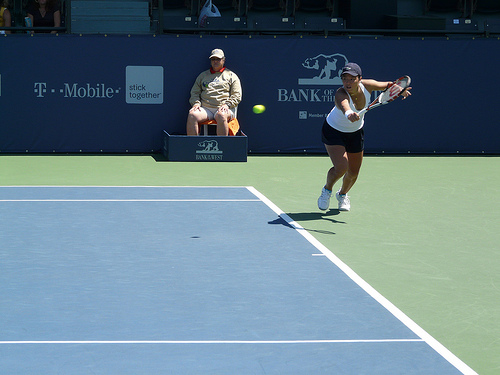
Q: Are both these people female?
A: No, they are both male and female.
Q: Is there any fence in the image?
A: No, there are no fences.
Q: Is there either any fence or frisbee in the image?
A: No, there are no fences or frisbees.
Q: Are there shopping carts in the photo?
A: No, there are no shopping carts.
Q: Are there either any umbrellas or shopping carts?
A: No, there are no shopping carts or umbrellas.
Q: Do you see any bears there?
A: Yes, there is a bear.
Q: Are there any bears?
A: Yes, there is a bear.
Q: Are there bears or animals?
A: Yes, there is a bear.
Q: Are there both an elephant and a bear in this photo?
A: No, there is a bear but no elephants.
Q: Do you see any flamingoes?
A: No, there are no flamingoes.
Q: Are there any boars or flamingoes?
A: No, there are no flamingoes or boars.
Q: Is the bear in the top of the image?
A: Yes, the bear is in the top of the image.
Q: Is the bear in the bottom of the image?
A: No, the bear is in the top of the image.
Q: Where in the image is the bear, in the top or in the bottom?
A: The bear is in the top of the image.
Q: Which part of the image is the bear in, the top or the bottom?
A: The bear is in the top of the image.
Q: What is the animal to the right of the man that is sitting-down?
A: The animal is a bear.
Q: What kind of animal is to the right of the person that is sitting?
A: The animal is a bear.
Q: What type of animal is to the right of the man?
A: The animal is a bear.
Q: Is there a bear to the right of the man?
A: Yes, there is a bear to the right of the man.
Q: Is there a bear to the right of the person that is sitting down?
A: Yes, there is a bear to the right of the man.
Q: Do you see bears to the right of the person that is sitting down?
A: Yes, there is a bear to the right of the man.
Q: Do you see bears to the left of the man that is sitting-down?
A: No, the bear is to the right of the man.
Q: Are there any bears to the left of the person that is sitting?
A: No, the bear is to the right of the man.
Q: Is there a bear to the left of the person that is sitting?
A: No, the bear is to the right of the man.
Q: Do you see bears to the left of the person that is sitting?
A: No, the bear is to the right of the man.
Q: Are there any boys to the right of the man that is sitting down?
A: No, there is a bear to the right of the man.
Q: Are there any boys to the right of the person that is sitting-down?
A: No, there is a bear to the right of the man.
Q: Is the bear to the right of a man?
A: Yes, the bear is to the right of a man.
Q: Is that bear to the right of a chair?
A: No, the bear is to the right of a man.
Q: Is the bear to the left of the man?
A: No, the bear is to the right of the man.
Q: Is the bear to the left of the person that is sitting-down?
A: No, the bear is to the right of the man.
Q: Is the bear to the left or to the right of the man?
A: The bear is to the right of the man.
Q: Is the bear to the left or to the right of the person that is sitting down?
A: The bear is to the right of the man.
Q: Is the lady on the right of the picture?
A: Yes, the lady is on the right of the image.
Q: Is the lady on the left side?
A: No, the lady is on the right of the image.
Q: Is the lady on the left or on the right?
A: The lady is on the right of the image.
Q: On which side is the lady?
A: The lady is on the right of the image.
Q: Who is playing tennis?
A: The lady is playing tennis.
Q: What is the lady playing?
A: The lady is playing tennis.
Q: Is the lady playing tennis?
A: Yes, the lady is playing tennis.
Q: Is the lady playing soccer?
A: No, the lady is playing tennis.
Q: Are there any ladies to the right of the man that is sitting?
A: Yes, there is a lady to the right of the man.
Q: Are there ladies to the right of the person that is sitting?
A: Yes, there is a lady to the right of the man.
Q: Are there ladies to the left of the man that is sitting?
A: No, the lady is to the right of the man.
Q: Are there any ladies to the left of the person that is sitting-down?
A: No, the lady is to the right of the man.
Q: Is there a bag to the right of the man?
A: No, there is a lady to the right of the man.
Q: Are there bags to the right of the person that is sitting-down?
A: No, there is a lady to the right of the man.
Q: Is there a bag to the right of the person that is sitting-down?
A: No, there is a lady to the right of the man.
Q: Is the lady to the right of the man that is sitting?
A: Yes, the lady is to the right of the man.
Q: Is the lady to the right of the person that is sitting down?
A: Yes, the lady is to the right of the man.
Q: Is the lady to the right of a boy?
A: No, the lady is to the right of the man.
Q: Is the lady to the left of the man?
A: No, the lady is to the right of the man.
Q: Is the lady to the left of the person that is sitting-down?
A: No, the lady is to the right of the man.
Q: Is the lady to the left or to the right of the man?
A: The lady is to the right of the man.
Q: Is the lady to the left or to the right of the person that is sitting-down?
A: The lady is to the right of the man.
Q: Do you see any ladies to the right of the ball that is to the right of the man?
A: Yes, there is a lady to the right of the ball.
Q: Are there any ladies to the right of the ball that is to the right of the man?
A: Yes, there is a lady to the right of the ball.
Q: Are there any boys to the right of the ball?
A: No, there is a lady to the right of the ball.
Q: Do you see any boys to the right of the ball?
A: No, there is a lady to the right of the ball.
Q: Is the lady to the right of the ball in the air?
A: Yes, the lady is to the right of the ball.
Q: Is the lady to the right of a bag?
A: No, the lady is to the right of the ball.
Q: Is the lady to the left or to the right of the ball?
A: The lady is to the right of the ball.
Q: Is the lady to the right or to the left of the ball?
A: The lady is to the right of the ball.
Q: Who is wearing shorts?
A: The lady is wearing shorts.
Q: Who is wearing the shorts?
A: The lady is wearing shorts.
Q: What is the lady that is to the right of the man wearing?
A: The lady is wearing shorts.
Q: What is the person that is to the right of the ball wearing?
A: The lady is wearing shorts.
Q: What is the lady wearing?
A: The lady is wearing shorts.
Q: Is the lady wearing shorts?
A: Yes, the lady is wearing shorts.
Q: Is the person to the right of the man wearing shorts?
A: Yes, the lady is wearing shorts.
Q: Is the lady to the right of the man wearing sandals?
A: No, the lady is wearing shorts.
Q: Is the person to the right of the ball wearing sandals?
A: No, the lady is wearing shorts.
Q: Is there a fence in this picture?
A: No, there are no fences.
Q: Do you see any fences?
A: No, there are no fences.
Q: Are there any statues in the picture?
A: No, there are no statues.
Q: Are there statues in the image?
A: No, there are no statues.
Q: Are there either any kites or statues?
A: No, there are no statues or kites.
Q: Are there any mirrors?
A: No, there are no mirrors.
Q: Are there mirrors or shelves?
A: No, there are no mirrors or shelves.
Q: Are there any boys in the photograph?
A: No, there are no boys.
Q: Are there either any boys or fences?
A: No, there are no boys or fences.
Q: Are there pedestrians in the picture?
A: No, there are no pedestrians.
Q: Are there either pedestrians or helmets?
A: No, there are no pedestrians or helmets.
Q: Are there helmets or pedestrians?
A: No, there are no pedestrians or helmets.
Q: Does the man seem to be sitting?
A: Yes, the man is sitting.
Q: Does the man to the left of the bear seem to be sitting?
A: Yes, the man is sitting.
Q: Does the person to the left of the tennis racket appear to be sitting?
A: Yes, the man is sitting.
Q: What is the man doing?
A: The man is sitting.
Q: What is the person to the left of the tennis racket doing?
A: The man is sitting.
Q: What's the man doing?
A: The man is sitting.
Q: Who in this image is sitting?
A: The man is sitting.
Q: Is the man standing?
A: No, the man is sitting.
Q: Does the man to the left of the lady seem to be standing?
A: No, the man is sitting.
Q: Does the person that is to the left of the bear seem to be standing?
A: No, the man is sitting.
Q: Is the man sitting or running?
A: The man is sitting.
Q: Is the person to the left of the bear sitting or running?
A: The man is sitting.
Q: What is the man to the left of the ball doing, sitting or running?
A: The man is sitting.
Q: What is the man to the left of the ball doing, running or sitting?
A: The man is sitting.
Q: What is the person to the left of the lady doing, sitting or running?
A: The man is sitting.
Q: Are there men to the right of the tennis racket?
A: No, the man is to the left of the tennis racket.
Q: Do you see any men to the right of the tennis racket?
A: No, the man is to the left of the tennis racket.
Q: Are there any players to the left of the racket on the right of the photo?
A: No, there is a man to the left of the tennis racket.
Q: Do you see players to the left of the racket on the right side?
A: No, there is a man to the left of the tennis racket.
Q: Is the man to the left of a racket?
A: Yes, the man is to the left of a racket.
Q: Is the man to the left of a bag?
A: No, the man is to the left of a racket.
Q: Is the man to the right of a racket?
A: No, the man is to the left of a racket.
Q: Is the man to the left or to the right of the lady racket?
A: The man is to the left of the tennis racket.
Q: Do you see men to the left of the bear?
A: Yes, there is a man to the left of the bear.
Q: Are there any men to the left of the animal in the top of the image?
A: Yes, there is a man to the left of the bear.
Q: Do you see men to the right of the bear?
A: No, the man is to the left of the bear.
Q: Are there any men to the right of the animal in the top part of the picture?
A: No, the man is to the left of the bear.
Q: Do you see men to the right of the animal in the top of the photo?
A: No, the man is to the left of the bear.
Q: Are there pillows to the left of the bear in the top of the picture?
A: No, there is a man to the left of the bear.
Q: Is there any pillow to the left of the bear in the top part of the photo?
A: No, there is a man to the left of the bear.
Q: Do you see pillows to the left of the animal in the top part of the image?
A: No, there is a man to the left of the bear.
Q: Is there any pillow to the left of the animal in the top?
A: No, there is a man to the left of the bear.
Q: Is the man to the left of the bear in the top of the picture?
A: Yes, the man is to the left of the bear.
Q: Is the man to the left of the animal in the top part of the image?
A: Yes, the man is to the left of the bear.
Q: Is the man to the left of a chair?
A: No, the man is to the left of the bear.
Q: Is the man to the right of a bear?
A: No, the man is to the left of a bear.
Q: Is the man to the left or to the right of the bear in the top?
A: The man is to the left of the bear.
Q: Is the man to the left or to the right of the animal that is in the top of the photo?
A: The man is to the left of the bear.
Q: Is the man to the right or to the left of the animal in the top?
A: The man is to the left of the bear.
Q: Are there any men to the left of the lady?
A: Yes, there is a man to the left of the lady.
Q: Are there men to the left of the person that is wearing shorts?
A: Yes, there is a man to the left of the lady.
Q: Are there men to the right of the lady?
A: No, the man is to the left of the lady.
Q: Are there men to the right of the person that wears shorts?
A: No, the man is to the left of the lady.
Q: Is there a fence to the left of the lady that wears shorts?
A: No, there is a man to the left of the lady.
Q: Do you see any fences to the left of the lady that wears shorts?
A: No, there is a man to the left of the lady.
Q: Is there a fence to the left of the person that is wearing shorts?
A: No, there is a man to the left of the lady.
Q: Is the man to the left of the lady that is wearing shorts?
A: Yes, the man is to the left of the lady.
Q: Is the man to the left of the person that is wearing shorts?
A: Yes, the man is to the left of the lady.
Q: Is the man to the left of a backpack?
A: No, the man is to the left of the lady.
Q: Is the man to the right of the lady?
A: No, the man is to the left of the lady.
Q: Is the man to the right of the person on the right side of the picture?
A: No, the man is to the left of the lady.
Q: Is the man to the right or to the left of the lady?
A: The man is to the left of the lady.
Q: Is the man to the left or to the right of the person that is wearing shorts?
A: The man is to the left of the lady.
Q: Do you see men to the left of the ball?
A: Yes, there is a man to the left of the ball.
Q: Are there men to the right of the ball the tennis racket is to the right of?
A: No, the man is to the left of the ball.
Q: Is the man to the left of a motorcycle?
A: No, the man is to the left of the ball.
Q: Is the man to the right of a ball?
A: No, the man is to the left of a ball.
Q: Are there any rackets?
A: Yes, there is a racket.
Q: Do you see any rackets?
A: Yes, there is a racket.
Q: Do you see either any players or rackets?
A: Yes, there is a racket.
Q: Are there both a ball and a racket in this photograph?
A: Yes, there are both a racket and a ball.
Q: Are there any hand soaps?
A: No, there are no hand soaps.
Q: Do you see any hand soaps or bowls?
A: No, there are no hand soaps or bowls.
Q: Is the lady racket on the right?
A: Yes, the tennis racket is on the right of the image.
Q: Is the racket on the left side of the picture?
A: No, the racket is on the right of the image.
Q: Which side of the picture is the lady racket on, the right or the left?
A: The racket is on the right of the image.